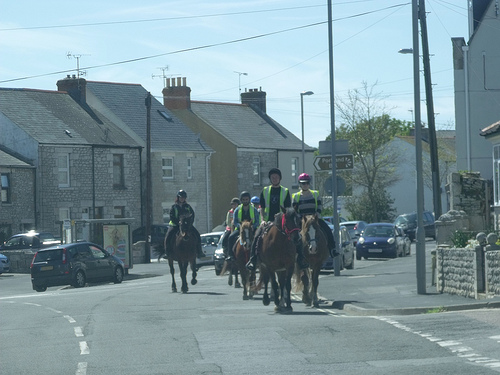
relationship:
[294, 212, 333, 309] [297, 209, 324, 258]
horse has head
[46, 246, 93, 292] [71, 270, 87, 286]
car has wheel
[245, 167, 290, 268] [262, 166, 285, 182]
man wearing helmet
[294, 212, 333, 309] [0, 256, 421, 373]
horse walking down road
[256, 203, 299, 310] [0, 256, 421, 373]
horse walking down road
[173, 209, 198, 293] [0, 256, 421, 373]
horse walking down road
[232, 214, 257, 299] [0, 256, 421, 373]
horse walking down road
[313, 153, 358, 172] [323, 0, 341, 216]
signs on a pole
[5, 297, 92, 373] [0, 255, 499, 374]
line on a street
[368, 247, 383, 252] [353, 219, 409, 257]
license plate on car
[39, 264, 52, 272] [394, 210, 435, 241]
license plate on vehicle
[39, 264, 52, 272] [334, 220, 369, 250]
license plate on vehicle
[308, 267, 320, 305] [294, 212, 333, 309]
leg of horse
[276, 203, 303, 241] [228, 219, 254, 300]
horsehead part of horse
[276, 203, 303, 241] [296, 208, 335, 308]
horsehead part of horse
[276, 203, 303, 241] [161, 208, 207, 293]
horsehead part of horse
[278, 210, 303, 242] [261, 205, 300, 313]
horsehead part of horse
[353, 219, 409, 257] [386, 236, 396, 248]
car has headlight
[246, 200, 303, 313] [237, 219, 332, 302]
horse has head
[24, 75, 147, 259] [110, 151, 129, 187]
building has window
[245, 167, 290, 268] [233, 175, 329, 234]
man wearing vest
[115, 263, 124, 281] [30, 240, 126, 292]
wheel of a car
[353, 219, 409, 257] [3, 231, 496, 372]
car on side of street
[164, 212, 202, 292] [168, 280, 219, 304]
horse has shadow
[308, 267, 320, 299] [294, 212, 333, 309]
leg on horse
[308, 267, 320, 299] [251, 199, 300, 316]
leg on horse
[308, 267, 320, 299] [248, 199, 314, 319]
leg on horse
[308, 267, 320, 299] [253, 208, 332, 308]
leg on horse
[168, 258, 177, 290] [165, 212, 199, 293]
leg on horse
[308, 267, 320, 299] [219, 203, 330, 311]
leg on horses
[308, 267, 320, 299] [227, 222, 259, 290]
leg on horse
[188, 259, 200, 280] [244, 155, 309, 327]
leg on horse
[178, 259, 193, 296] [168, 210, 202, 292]
leg on horse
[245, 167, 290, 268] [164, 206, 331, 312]
man riding on horses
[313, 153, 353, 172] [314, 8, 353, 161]
signs on pole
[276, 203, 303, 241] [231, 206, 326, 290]
horsehead on horse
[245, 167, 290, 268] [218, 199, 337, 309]
man riding horses